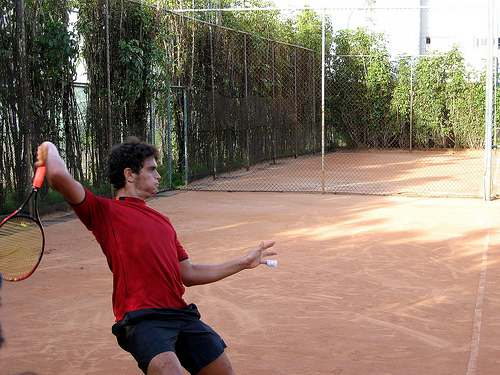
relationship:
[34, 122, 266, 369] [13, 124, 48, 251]
man playing tennis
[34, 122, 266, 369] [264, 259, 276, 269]
man has band-aid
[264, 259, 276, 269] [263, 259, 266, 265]
band-aid on finger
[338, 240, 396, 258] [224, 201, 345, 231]
floor of court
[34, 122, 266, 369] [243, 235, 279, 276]
man has hand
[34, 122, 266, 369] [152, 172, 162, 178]
man has nose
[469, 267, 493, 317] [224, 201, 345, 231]
line on court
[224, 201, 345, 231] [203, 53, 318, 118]
court has fence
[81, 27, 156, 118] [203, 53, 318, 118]
trees surround fence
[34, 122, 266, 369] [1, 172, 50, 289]
man has tennis racket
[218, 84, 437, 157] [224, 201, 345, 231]
net dividing court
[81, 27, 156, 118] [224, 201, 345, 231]
trees beside court